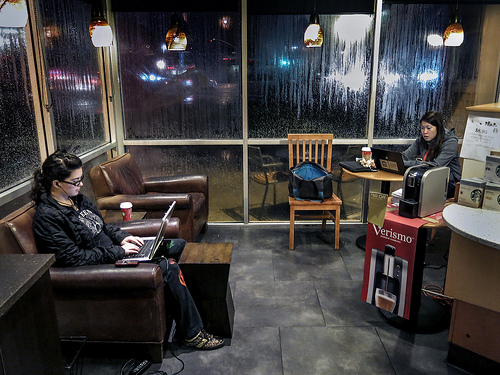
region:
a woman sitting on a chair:
[12, 143, 201, 374]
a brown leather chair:
[91, 136, 208, 234]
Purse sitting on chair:
[286, 160, 334, 198]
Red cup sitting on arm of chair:
[122, 200, 133, 220]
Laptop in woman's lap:
[130, 200, 176, 265]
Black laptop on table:
[372, 146, 417, 172]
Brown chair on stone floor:
[285, 134, 340, 244]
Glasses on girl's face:
[63, 176, 85, 186]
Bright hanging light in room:
[85, 18, 111, 49]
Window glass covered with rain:
[385, 12, 462, 128]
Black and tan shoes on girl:
[185, 330, 222, 347]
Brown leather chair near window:
[99, 150, 213, 229]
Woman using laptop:
[29, 146, 229, 359]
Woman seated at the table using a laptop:
[344, 109, 463, 203]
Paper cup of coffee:
[118, 199, 134, 225]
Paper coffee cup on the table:
[360, 144, 372, 171]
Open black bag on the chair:
[284, 151, 341, 208]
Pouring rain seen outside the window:
[0, 15, 450, 182]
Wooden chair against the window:
[285, 130, 340, 251]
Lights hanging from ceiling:
[0, 1, 487, 48]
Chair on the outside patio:
[247, 143, 289, 215]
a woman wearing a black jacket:
[31, 150, 225, 350]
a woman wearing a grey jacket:
[402, 112, 460, 182]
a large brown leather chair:
[0, 200, 181, 366]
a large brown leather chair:
[90, 153, 209, 242]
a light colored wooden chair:
[286, 134, 341, 251]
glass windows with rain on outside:
[2, 42, 498, 224]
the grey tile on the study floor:
[85, 226, 467, 372]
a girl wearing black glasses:
[31, 150, 224, 350]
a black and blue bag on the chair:
[286, 163, 335, 201]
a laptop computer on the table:
[369, 146, 407, 173]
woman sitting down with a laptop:
[1, 157, 233, 307]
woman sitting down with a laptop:
[377, 110, 456, 175]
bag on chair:
[287, 159, 331, 202]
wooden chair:
[288, 122, 345, 250]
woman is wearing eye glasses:
[44, 148, 96, 197]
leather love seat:
[98, 150, 225, 212]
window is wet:
[268, 57, 350, 99]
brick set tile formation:
[252, 260, 368, 366]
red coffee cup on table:
[346, 139, 375, 171]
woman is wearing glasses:
[56, 174, 87, 190]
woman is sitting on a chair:
[2, 156, 233, 363]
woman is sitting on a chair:
[393, 109, 465, 201]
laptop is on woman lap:
[33, 157, 182, 270]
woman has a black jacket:
[35, 192, 128, 262]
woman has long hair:
[25, 150, 86, 200]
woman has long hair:
[416, 109, 443, 155]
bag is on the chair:
[285, 133, 340, 247]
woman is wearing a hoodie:
[405, 128, 460, 182]